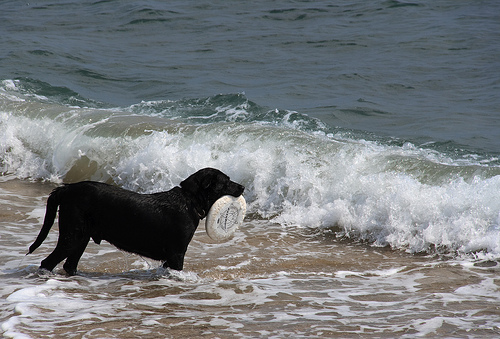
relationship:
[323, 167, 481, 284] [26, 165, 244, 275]
water beneath dog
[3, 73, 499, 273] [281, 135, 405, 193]
wave in water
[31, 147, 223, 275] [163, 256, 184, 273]
dog has leg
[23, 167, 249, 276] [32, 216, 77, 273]
dog has leg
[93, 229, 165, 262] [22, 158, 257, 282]
stomach on dog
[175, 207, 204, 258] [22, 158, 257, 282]
chest on dog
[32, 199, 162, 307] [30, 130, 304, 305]
leg on dog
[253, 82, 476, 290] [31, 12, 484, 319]
wave on water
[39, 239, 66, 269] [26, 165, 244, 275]
leg on dog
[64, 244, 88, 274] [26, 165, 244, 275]
leg on dog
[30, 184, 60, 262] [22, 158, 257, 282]
tail of a dog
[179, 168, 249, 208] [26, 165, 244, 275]
head of a dog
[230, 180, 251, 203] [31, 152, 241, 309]
snout of a dog